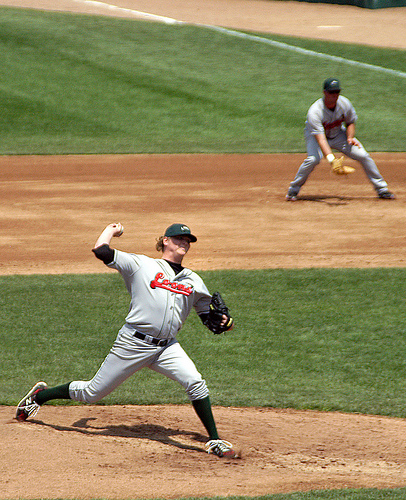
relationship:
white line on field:
[83, 0, 404, 80] [4, 1, 404, 316]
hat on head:
[165, 221, 198, 244] [157, 222, 192, 262]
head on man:
[157, 222, 192, 262] [16, 212, 247, 460]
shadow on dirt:
[28, 410, 215, 462] [1, 399, 404, 497]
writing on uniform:
[150, 273, 193, 299] [66, 242, 216, 421]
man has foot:
[13, 218, 240, 463] [203, 436, 240, 461]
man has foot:
[13, 218, 240, 463] [2, 375, 58, 421]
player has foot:
[283, 71, 395, 201] [277, 186, 302, 207]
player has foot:
[283, 71, 395, 201] [377, 189, 395, 204]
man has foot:
[13, 218, 240, 463] [171, 394, 260, 460]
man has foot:
[13, 218, 240, 463] [12, 381, 53, 428]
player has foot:
[283, 71, 395, 201] [279, 186, 302, 203]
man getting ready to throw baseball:
[13, 218, 287, 473] [112, 224, 124, 237]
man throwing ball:
[13, 218, 240, 463] [103, 220, 128, 238]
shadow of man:
[25, 416, 213, 455] [13, 218, 240, 463]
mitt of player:
[328, 155, 354, 175] [285, 80, 394, 206]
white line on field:
[84, 1, 404, 80] [1, 0, 401, 497]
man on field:
[13, 218, 240, 463] [1, 0, 401, 497]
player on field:
[283, 71, 386, 199] [1, 0, 401, 497]